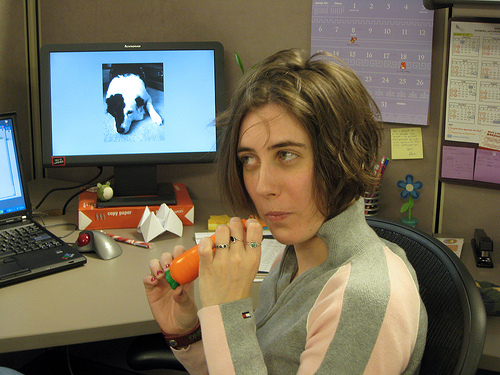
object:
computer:
[0, 112, 86, 289]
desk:
[2, 181, 247, 352]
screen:
[40, 40, 222, 164]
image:
[101, 62, 165, 139]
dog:
[104, 70, 164, 134]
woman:
[140, 45, 430, 373]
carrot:
[160, 218, 266, 289]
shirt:
[170, 200, 429, 374]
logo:
[239, 309, 255, 320]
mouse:
[73, 227, 123, 261]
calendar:
[306, 1, 435, 125]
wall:
[1, 2, 499, 243]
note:
[390, 125, 426, 160]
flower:
[394, 172, 424, 201]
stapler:
[471, 225, 494, 269]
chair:
[366, 214, 491, 374]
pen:
[101, 226, 152, 251]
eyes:
[236, 151, 260, 170]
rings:
[244, 240, 262, 249]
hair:
[211, 48, 385, 218]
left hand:
[196, 214, 267, 305]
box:
[77, 182, 195, 230]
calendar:
[442, 19, 499, 145]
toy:
[136, 203, 186, 242]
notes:
[435, 145, 499, 186]